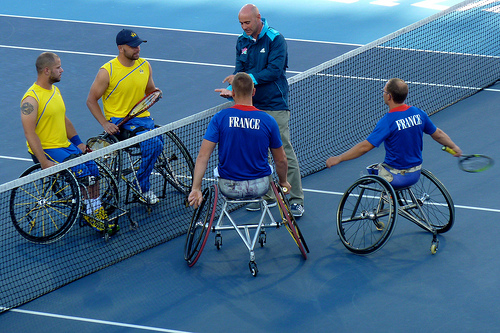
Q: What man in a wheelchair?
A: Man with tennis racket.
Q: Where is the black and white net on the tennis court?
A: Where five persons are.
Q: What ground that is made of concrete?
A: The blue ground.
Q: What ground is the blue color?
A: Tennis court.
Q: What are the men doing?
A: Playing tennis.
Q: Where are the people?
A: At the tennis court.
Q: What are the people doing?
A: Playing tennis.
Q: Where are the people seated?
A: On a wheelchair.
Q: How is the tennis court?
A: Blue.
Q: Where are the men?
A: On wheelchairs.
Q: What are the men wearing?
A: Blue and yellow tshirts.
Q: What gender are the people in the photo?
A: Male.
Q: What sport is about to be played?
A: Tennis.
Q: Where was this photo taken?
A: At a tennis court.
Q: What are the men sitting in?
A: Wheelchairs.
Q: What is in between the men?
A: A net.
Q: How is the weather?
A: Sunny.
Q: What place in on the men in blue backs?
A: France.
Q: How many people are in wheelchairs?
A: Four.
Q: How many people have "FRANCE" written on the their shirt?
A: Two.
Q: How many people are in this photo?
A: Five.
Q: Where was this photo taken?
A: During a tennis game.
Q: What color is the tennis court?
A: Blue.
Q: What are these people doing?
A: Playing tennis.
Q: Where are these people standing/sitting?
A: On a tennis court.